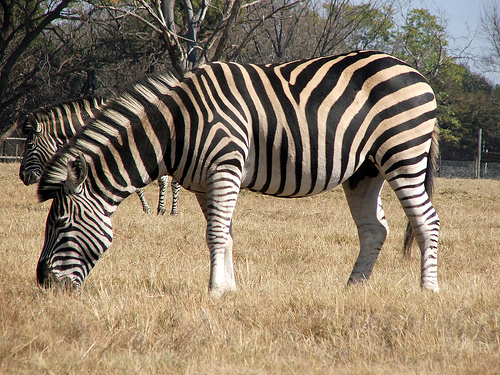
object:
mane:
[35, 65, 187, 202]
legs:
[157, 171, 168, 214]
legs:
[135, 187, 151, 213]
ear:
[65, 150, 89, 194]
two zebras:
[17, 49, 440, 299]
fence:
[0, 128, 500, 179]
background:
[0, 0, 499, 178]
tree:
[99, 0, 320, 80]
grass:
[0, 161, 499, 375]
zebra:
[35, 49, 440, 300]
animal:
[19, 94, 181, 217]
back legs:
[341, 144, 441, 295]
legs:
[194, 161, 244, 293]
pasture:
[0, 0, 500, 375]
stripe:
[252, 61, 322, 197]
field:
[0, 146, 500, 375]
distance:
[0, 122, 498, 194]